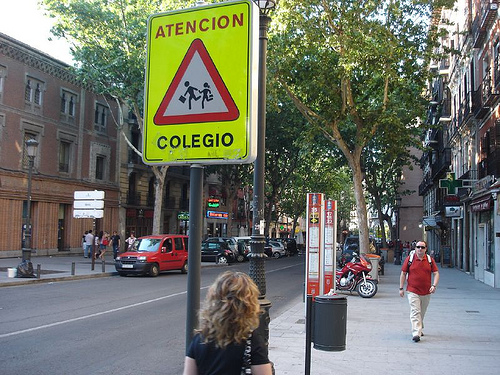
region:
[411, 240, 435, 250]
man wearing sunglasses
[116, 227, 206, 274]
red van parked on street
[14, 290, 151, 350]
white line running down street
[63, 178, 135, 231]
tall white street sign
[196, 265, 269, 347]
woman's long blond hair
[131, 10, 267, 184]
yellow and red street sign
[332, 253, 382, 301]
red bike parked on sidewalk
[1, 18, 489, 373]
a scene during the day time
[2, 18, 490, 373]
an image downtown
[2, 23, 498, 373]
a scene outside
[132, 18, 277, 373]
a green street sign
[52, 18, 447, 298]
a row of green trees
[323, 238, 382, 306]
a red bike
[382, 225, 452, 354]
a person walking down the street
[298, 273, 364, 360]
a gray trashcan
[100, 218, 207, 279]
a red car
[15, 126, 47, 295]
a street light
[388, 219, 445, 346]
man at the sidewalk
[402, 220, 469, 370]
man at the sidewalk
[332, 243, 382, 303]
motorcycle is parked at the sidewalk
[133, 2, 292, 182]
neon green sign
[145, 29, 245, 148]
red triangle on sign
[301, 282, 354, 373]
black garbage can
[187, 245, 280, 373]
lady wearing black shirt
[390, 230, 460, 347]
man walking along side walk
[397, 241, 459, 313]
man wearing red shirt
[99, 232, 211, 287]
red van parked at side of road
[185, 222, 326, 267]
cars parked along road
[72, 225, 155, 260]
people walking along side walk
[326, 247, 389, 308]
red motorcycle parked on side walk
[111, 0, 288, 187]
neon green sign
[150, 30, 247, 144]
red triangle on sign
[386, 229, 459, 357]
man walking on side walk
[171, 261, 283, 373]
lady walking on side walk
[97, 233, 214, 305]
red van parked on side of the road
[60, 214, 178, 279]
people walking on side walk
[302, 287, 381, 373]
black garbage can on side walk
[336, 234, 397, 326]
red motorcycle parked on the side walk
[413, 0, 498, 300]
apartment building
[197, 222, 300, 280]
cars parked on the street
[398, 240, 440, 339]
man in red shirt and khakis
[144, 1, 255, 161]
green and red warning sign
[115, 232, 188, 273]
red car parked on street